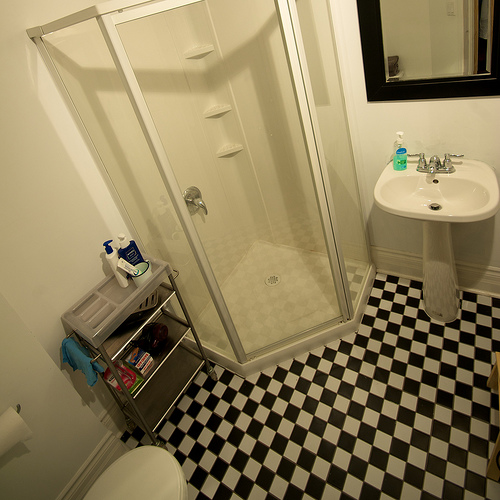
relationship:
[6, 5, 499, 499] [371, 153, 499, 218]
shower room has sink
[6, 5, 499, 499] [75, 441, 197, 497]
shower room has toilet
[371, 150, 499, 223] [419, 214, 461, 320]
sink has pedestal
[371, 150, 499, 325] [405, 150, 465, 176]
sink has faucet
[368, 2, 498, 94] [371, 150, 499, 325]
mirror above sink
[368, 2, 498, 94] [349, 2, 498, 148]
mirror on wall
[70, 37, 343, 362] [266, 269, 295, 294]
shower has drainage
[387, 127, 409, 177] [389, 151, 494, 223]
dispenser on sink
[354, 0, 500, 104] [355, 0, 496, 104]
mirror has frames